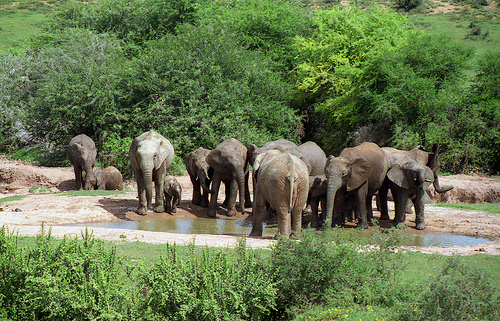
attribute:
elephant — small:
[316, 137, 393, 231]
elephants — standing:
[89, 123, 480, 194]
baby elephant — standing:
[162, 174, 182, 214]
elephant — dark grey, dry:
[66, 135, 95, 190]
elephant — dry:
[186, 142, 216, 207]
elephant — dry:
[252, 142, 303, 239]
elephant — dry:
[318, 134, 385, 224]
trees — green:
[3, 3, 497, 195]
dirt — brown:
[33, 193, 161, 244]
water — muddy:
[196, 220, 219, 228]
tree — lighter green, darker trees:
[292, 5, 406, 125]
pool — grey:
[79, 172, 498, 264]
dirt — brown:
[1, 197, 113, 223]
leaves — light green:
[297, 22, 393, 106]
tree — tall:
[335, 22, 459, 127]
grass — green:
[118, 247, 155, 259]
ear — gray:
[344, 150, 373, 195]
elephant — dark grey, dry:
[125, 127, 177, 212]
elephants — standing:
[59, 119, 464, 241]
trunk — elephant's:
[323, 180, 338, 230]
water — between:
[151, 204, 229, 237]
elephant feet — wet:
[132, 200, 172, 218]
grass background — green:
[18, 15, 498, 131]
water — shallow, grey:
[64, 209, 496, 244]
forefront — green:
[15, 209, 483, 305]